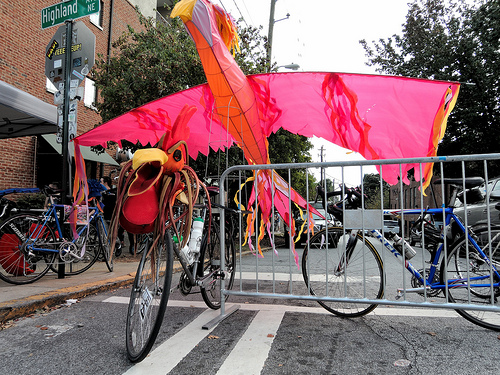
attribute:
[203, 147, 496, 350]
ack — white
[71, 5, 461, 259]
bird kite — long 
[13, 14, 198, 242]
building — brown, brick